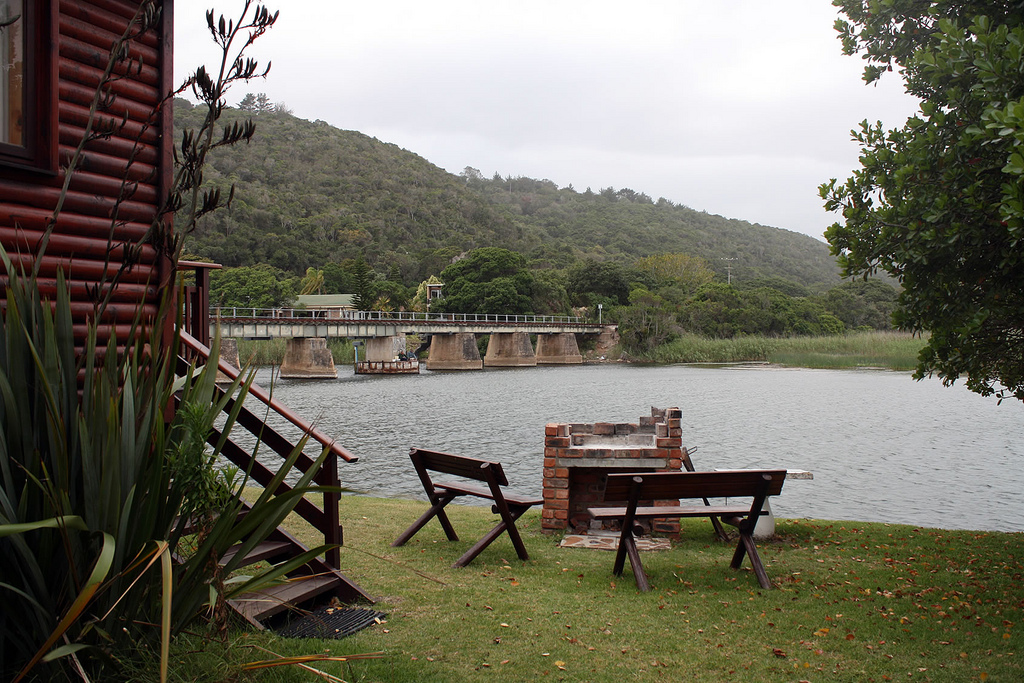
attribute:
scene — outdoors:
[7, 8, 1009, 669]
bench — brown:
[592, 472, 785, 590]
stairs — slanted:
[175, 317, 387, 650]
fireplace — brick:
[394, 404, 774, 586]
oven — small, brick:
[383, 404, 840, 602]